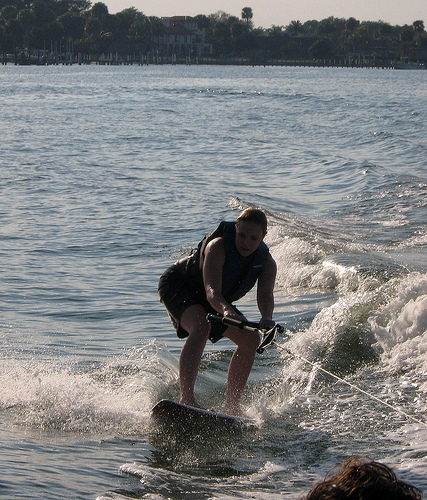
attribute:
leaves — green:
[1, 1, 426, 69]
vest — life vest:
[187, 208, 271, 308]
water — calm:
[38, 63, 201, 221]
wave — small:
[207, 195, 424, 462]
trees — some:
[0, 0, 426, 64]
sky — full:
[81, 0, 426, 28]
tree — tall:
[358, 15, 408, 79]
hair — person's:
[234, 205, 271, 231]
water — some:
[66, 35, 422, 213]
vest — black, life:
[191, 216, 278, 319]